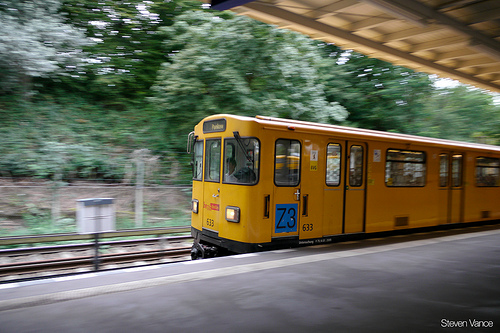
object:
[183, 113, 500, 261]
train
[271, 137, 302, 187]
window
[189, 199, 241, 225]
front lights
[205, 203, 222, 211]
red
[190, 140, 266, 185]
windows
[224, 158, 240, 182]
driver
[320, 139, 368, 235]
doors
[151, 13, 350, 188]
trees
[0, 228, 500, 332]
floor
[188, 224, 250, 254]
edge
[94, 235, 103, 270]
post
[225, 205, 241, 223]
headlight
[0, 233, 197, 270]
track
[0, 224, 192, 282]
tracks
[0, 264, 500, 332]
ground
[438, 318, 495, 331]
writing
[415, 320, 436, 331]
corner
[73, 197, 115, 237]
sign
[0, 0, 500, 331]
station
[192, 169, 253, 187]
windshield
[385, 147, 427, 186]
side window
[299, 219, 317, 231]
number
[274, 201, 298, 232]
notation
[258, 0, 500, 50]
shade